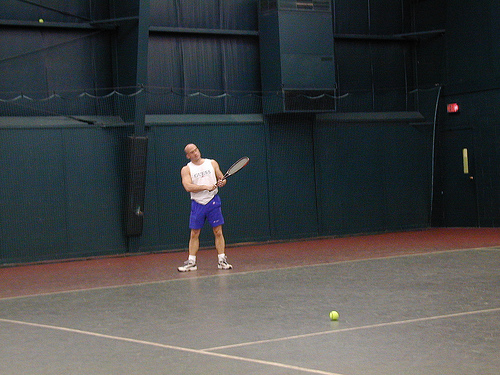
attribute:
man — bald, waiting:
[180, 143, 235, 274]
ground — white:
[1, 225, 499, 373]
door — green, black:
[441, 128, 482, 229]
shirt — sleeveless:
[181, 158, 224, 205]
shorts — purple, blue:
[183, 197, 224, 230]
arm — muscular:
[178, 160, 214, 196]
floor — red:
[6, 227, 500, 305]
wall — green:
[261, 131, 393, 259]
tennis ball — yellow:
[323, 305, 346, 325]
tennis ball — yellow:
[327, 305, 341, 321]